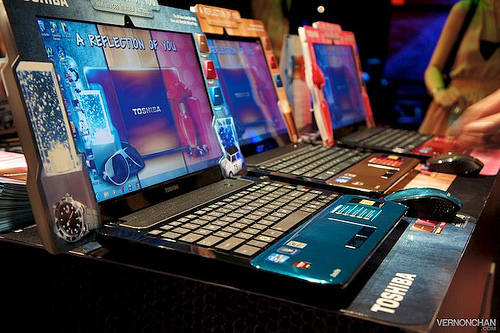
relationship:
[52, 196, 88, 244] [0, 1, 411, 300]
compass on laptop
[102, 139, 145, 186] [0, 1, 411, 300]
sunglasses on laptop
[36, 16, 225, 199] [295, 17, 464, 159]
screen on computer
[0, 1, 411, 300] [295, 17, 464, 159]
laptop by computer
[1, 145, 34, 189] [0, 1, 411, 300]
paper behind laptop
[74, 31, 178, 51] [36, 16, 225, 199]
wording on screen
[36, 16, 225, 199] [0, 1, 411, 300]
screen on laptop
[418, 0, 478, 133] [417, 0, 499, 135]
purse on lady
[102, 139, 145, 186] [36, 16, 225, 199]
sunglasses on screen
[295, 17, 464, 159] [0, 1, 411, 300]
computer by laptop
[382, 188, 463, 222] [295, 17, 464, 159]
mouse by computer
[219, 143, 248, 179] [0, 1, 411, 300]
car on laptop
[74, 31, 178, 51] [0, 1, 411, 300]
wording on laptop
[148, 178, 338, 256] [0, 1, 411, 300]
keyboard on laptop